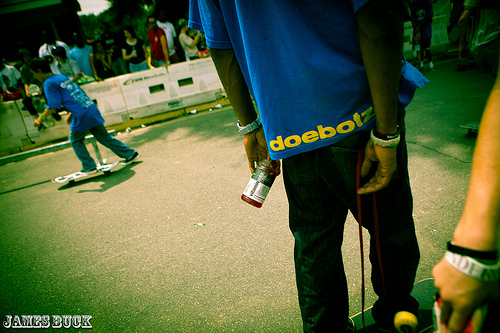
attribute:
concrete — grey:
[73, 195, 280, 308]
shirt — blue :
[38, 72, 108, 127]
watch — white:
[235, 111, 267, 136]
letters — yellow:
[272, 105, 372, 154]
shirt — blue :
[189, 1, 423, 150]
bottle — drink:
[235, 147, 294, 209]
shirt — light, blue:
[68, 45, 97, 78]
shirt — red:
[147, 31, 171, 63]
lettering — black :
[445, 250, 498, 282]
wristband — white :
[440, 242, 498, 281]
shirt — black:
[121, 38, 145, 59]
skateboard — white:
[50, 150, 136, 190]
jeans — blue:
[256, 140, 423, 285]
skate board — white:
[50, 157, 122, 187]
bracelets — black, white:
[311, 114, 444, 172]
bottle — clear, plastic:
[239, 147, 279, 209]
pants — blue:
[258, 107, 423, 332]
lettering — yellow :
[264, 107, 378, 152]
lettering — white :
[60, 79, 93, 110]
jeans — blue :
[70, 110, 136, 175]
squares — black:
[54, 169, 111, 181]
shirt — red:
[146, 27, 166, 62]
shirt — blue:
[42, 73, 104, 131]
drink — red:
[238, 157, 282, 211]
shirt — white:
[37, 40, 67, 70]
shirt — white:
[154, 20, 174, 56]